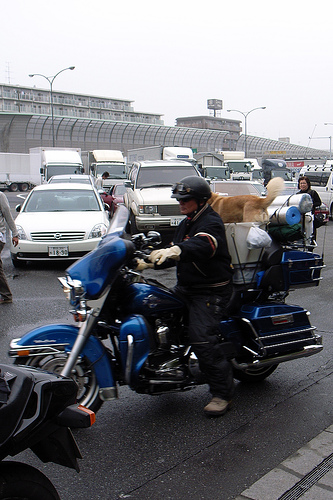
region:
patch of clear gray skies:
[1, 6, 331, 41]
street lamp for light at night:
[34, 65, 73, 142]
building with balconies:
[0, 82, 167, 121]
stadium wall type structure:
[60, 117, 216, 142]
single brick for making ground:
[241, 464, 296, 498]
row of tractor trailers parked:
[203, 148, 290, 178]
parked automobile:
[21, 182, 95, 246]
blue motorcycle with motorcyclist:
[21, 183, 324, 388]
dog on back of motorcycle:
[209, 184, 274, 232]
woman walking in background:
[296, 176, 323, 239]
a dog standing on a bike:
[215, 184, 274, 258]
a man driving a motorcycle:
[86, 204, 270, 359]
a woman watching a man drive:
[289, 165, 330, 229]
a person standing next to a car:
[93, 166, 133, 200]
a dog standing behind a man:
[209, 181, 273, 236]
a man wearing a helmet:
[170, 177, 233, 238]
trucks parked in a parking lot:
[32, 150, 248, 174]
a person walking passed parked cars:
[1, 180, 42, 311]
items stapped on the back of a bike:
[259, 189, 321, 294]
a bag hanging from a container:
[244, 218, 287, 266]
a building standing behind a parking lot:
[19, 86, 173, 136]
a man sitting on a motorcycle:
[133, 176, 255, 420]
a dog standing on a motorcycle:
[209, 185, 299, 255]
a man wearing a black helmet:
[156, 163, 215, 241]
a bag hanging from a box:
[234, 226, 283, 258]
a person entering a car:
[94, 165, 120, 212]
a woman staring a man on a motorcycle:
[272, 164, 322, 264]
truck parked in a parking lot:
[53, 146, 269, 175]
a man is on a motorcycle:
[17, 175, 322, 417]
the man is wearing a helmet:
[172, 175, 211, 205]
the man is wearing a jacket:
[165, 205, 233, 288]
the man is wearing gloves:
[138, 238, 180, 269]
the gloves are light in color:
[135, 241, 179, 275]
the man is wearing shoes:
[204, 392, 232, 414]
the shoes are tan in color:
[203, 390, 229, 416]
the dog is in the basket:
[200, 173, 282, 233]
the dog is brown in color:
[202, 174, 280, 234]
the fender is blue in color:
[16, 316, 116, 390]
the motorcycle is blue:
[31, 120, 324, 410]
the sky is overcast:
[106, 65, 305, 158]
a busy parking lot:
[63, 120, 240, 354]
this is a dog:
[197, 170, 301, 228]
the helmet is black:
[150, 156, 223, 232]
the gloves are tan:
[144, 233, 201, 277]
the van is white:
[144, 126, 263, 292]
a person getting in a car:
[87, 173, 142, 217]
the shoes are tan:
[190, 377, 268, 440]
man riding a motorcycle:
[110, 188, 271, 399]